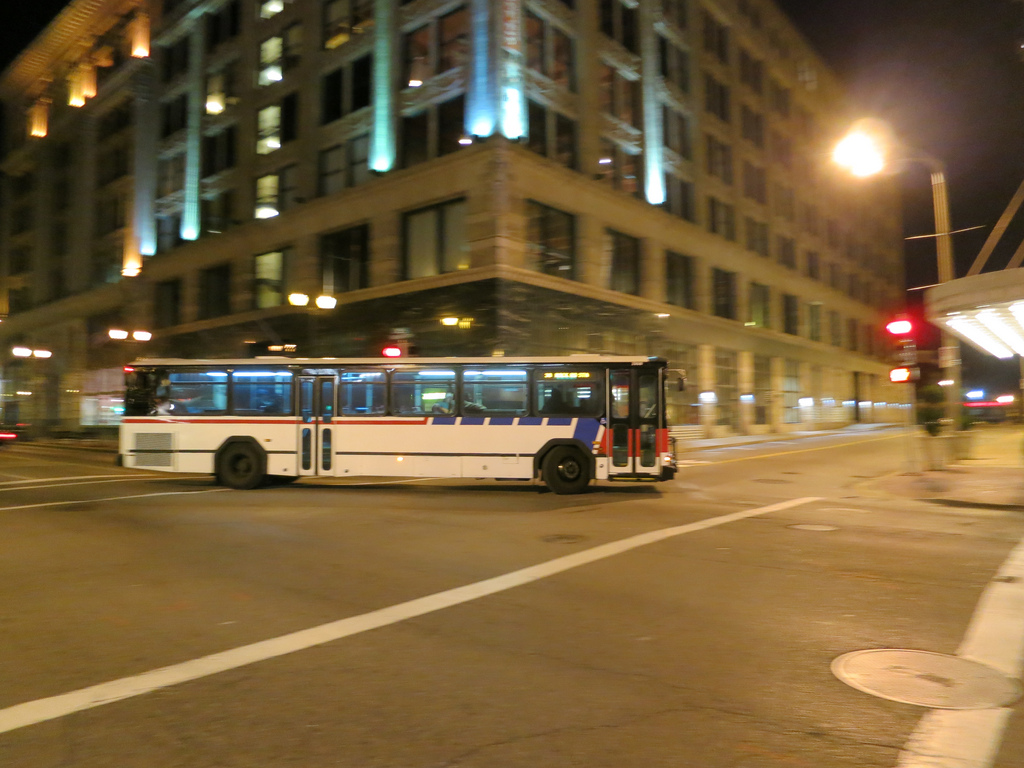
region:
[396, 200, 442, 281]
widow facing city intersection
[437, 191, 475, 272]
widow facing city intersection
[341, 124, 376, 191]
widow facing city intersection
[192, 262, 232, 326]
widow facing city intersection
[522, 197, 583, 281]
widow facing city intersection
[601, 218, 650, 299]
widow facing city intersection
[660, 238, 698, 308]
widow facing city intersection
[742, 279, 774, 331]
widow facing city intersection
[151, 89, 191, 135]
window on side of building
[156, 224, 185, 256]
window on side of building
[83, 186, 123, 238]
window on side of building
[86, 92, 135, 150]
window on side of building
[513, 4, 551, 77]
window on side of building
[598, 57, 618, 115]
window on side of building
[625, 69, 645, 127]
window on side of building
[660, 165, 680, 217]
window on side of building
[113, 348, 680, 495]
the bus in the intersection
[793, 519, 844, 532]
the man hole cover in the crosswalk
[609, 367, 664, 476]
the door on the front of the bus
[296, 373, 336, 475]
the door on the back of the bus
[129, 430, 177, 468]
the vent on the back of the bus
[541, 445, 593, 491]
the front tire on the bus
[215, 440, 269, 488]
the back tire of the bus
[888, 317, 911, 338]
the round red light is glaring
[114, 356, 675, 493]
bus is white with blue and red stripe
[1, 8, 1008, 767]
picture is night time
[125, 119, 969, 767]
light for the street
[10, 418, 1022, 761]
street is blacktop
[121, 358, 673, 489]
bus has 2 doors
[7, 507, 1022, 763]
street crosswalk is outlined with white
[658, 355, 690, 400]
mirror on the bus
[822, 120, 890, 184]
bright blurry yellow light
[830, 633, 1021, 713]
cover leading to sewer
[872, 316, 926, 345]
blurry red traffic light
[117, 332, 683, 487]
bus for public transportation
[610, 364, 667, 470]
entry and exit doors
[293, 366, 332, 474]
exit doors on bus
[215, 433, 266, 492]
rear tire on bus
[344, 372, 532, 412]
windows on city bus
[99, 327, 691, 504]
A long city bus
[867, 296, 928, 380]
A traffic light is lit red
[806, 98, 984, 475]
A street light is turned on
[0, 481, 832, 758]
White line on the street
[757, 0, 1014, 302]
The sky is very dark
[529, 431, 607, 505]
A black rubber bus tire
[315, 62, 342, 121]
a window on a building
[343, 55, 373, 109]
a window on a building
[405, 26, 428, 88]
a window on a building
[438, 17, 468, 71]
a window on a building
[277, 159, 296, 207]
a window on a building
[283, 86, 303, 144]
a window on a building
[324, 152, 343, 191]
a window on a building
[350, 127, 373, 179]
a window on a building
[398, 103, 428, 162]
a window on a building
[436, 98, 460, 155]
a window on a building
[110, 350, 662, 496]
a bus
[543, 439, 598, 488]
front wheel on the bus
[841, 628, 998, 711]
top of the sewer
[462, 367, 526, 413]
window on the bus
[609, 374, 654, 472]
door on the bus